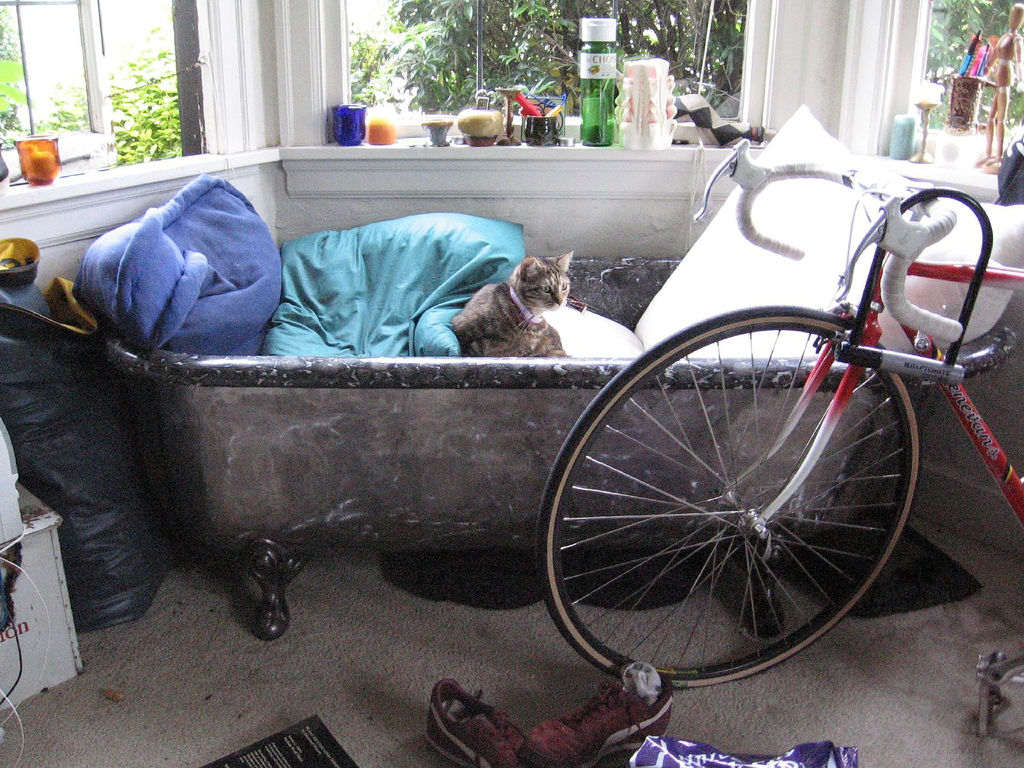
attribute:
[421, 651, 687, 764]
shoes — MANS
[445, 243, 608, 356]
cat — TAN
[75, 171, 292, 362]
pillow — BLUE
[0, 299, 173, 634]
bag — LARGE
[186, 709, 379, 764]
book — BLACK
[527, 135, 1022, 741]
bike — RED, ROAD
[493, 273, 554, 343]
collar — PURPLE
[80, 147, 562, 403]
pillows — blue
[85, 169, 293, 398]
pillow — blue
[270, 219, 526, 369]
pillow — aqua blue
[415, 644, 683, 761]
shoes — maroon and white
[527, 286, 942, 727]
tire — large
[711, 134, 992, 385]
handlebars — white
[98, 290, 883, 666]
claw tub — gray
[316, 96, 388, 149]
cup — blue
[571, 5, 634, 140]
bottle — green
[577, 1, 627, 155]
bottle — green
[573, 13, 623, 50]
cap — white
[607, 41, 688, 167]
decorative candle — large and white